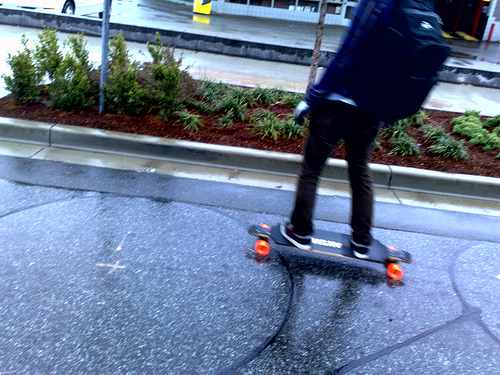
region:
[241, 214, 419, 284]
skateboard with orange wheels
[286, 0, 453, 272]
person on a skateboard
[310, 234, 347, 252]
white writing on a skateboard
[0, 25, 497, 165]
plants in the median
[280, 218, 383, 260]
pair of black skate shoes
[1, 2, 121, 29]
white car parked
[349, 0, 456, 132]
navy colored backpack on the skater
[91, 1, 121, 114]
metal post in the median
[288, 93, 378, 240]
skater's black colored pants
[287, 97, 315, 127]
gloves on the skater's hand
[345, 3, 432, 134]
boy has black backpack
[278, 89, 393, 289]
boy has black jeans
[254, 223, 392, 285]
black and white shoes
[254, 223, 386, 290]
boy on black skateboard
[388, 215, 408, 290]
large orange wheels on board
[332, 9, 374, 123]
boy has blue shirt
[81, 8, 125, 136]
grey pole near boy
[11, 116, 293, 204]
grey sidewalk on curb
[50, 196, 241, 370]
dark and grey road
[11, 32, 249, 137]
green plants near road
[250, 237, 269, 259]
wheel on a skateboard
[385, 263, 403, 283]
the wheel is orange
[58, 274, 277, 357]
the ground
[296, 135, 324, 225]
a person wearing pants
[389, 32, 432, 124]
a blue backpack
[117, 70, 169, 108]
the green plants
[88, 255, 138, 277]
a marking on the sidewalk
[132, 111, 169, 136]
the brown dirt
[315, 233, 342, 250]
logo on the skateboard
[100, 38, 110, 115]
a metal pole in the dirt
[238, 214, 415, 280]
black skate board on ground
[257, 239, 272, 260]
large orange front wheel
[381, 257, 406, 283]
large orange back wheel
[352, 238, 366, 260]
black and white skate shoes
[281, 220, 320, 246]
black and white skate shoes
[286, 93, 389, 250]
black skate pants on legs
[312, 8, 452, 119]
black backpack on man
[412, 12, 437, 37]
white logo on back pack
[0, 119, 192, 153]
concrete curb by road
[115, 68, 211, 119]
plants and bushes in dirt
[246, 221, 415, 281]
A black skateboard with four wheels.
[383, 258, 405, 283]
One bright orange wheel.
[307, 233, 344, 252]
A white logo on skateboard.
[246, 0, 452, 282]
A person riding a skateboard.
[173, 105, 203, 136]
A green growing plant.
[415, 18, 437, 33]
A logo on a book bag.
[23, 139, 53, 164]
A crack in the pavement.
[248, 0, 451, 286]
A person wearing a book bag.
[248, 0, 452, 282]
A person wearing black pants.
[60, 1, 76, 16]
The tire of a white vehicle.